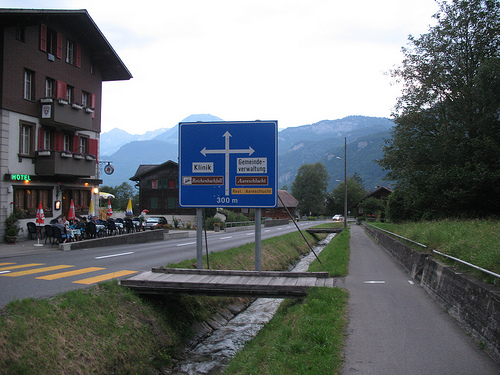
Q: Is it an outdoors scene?
A: Yes, it is outdoors.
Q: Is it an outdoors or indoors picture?
A: It is outdoors.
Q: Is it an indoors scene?
A: No, it is outdoors.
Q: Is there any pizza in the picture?
A: No, there are no pizzas.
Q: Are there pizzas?
A: No, there are no pizzas.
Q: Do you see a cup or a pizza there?
A: No, there are no pizzas or cups.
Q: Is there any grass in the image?
A: Yes, there is grass.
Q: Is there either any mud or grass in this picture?
A: Yes, there is grass.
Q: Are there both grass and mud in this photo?
A: No, there is grass but no mud.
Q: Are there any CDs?
A: No, there are no cds.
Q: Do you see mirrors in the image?
A: No, there are no mirrors.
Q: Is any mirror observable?
A: No, there are no mirrors.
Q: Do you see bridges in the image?
A: Yes, there is a bridge.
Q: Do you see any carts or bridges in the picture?
A: Yes, there is a bridge.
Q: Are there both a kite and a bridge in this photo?
A: No, there is a bridge but no kites.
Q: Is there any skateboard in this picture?
A: No, there are no skateboards.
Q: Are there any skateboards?
A: No, there are no skateboards.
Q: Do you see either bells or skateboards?
A: No, there are no skateboards or bells.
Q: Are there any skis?
A: No, there are no skis.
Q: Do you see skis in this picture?
A: No, there are no skis.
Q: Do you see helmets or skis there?
A: No, there are no skis or helmets.